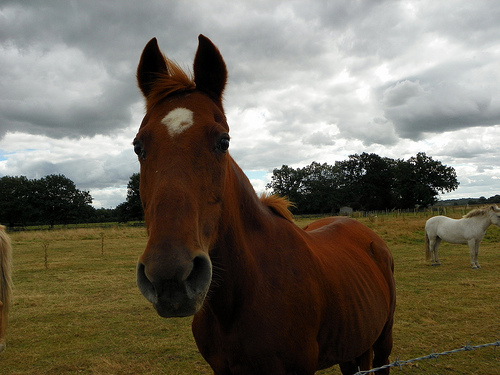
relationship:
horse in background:
[132, 34, 397, 374] [1, 116, 499, 286]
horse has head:
[132, 34, 397, 374] [133, 31, 230, 319]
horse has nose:
[132, 34, 397, 374] [139, 251, 216, 321]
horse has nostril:
[132, 34, 397, 374] [181, 252, 214, 301]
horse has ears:
[132, 34, 397, 374] [133, 31, 230, 104]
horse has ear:
[132, 34, 397, 374] [193, 32, 229, 101]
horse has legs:
[132, 34, 397, 374] [337, 353, 383, 374]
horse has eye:
[132, 34, 397, 374] [213, 130, 230, 154]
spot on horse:
[159, 106, 197, 139] [132, 34, 397, 374]